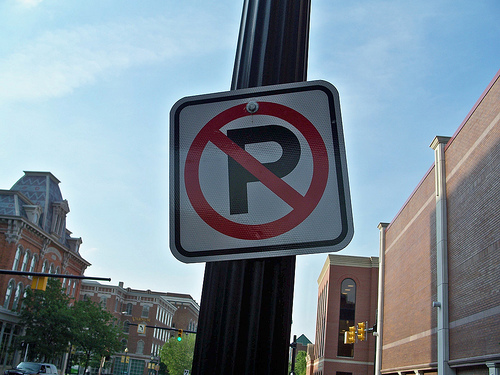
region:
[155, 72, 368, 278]
sign on black pole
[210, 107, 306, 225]
black letter with red line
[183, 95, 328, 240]
red circle around black letter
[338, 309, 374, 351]
two yellow traffic lights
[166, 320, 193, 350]
glowing green traffic light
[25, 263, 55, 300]
back of traffic light on pole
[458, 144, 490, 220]
shadow on red brick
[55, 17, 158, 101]
thin white clouds in daytime sky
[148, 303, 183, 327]
windows on top floor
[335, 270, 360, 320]
arch shaped window on building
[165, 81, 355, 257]
red white and black sign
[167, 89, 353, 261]
red white and black No sign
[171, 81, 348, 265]
no parking sign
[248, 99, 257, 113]
metal screw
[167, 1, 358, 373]
no parking sign attached to a black pole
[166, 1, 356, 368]
sign on a black pole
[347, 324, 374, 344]
couple of yellow traffic lights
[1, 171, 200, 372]
large brown buildings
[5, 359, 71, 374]
parked darked color vehicle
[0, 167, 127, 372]
trees in front of a building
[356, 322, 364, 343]
yellow traffic signal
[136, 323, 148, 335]
black and white left turn sign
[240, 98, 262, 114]
silver bolt securing sign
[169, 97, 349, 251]
black and white no parking sign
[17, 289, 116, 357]
trees with green leaves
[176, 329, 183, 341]
traffic light signalling green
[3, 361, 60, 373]
black vehicle driving on road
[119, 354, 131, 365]
flags hanging on light pole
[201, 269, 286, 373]
black metal sign pole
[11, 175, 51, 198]
design on building roof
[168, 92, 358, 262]
The sign is white, black and red.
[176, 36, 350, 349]
The sign is on a pole.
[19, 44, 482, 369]
It is daytime in the city.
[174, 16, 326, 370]
The pole is tall.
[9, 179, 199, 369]
The buildings are old.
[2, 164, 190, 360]
The buildings are brick and wood.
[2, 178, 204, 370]
The buildings are red and white.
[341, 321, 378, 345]
The street light is yellow.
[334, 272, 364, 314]
The lights are on.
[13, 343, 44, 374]
The car is moving.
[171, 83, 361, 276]
No parking sign on pole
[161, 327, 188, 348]
Traffic signal light on pole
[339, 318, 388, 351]
two traffic signal lights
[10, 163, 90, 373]
tall red brick building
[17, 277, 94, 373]
trees on the curb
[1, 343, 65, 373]
car parked on the street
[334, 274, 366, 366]
tall arched window on building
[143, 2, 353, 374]
tall black street pole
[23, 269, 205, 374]
row of red brick buildings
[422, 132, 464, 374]
tall white column on building